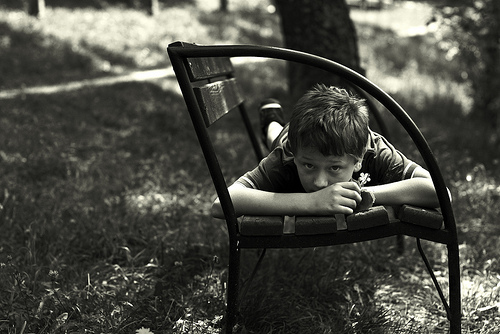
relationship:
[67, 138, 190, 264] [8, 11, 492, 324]
grass on hill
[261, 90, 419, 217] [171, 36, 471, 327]
boy on top of bench